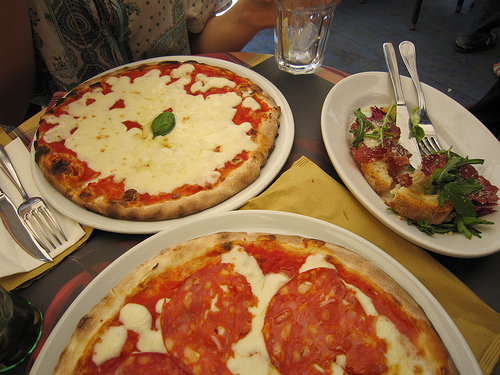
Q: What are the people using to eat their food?
A: Knives and forks.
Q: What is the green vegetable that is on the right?
A: Arugula.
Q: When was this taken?
A: During the day.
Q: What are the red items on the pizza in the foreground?
A: Salami.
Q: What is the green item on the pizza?
A: Basil.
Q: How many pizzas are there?
A: Two.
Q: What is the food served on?
A: Plates.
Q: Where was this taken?
A: At a restaurant.